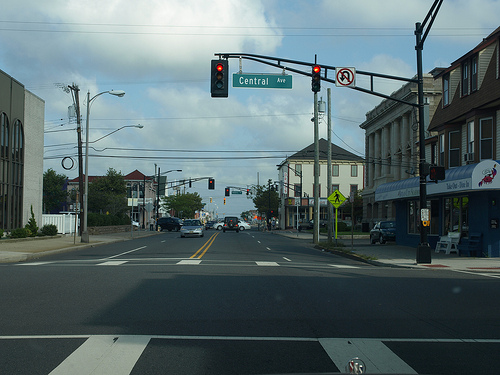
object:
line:
[0, 334, 500, 343]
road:
[1, 215, 499, 374]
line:
[107, 245, 149, 259]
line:
[282, 256, 292, 262]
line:
[197, 232, 220, 259]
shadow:
[76, 269, 499, 373]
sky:
[1, 0, 500, 219]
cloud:
[316, 0, 497, 39]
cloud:
[0, 0, 290, 88]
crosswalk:
[8, 258, 387, 271]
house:
[275, 136, 369, 231]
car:
[179, 219, 205, 239]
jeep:
[222, 216, 240, 233]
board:
[232, 72, 293, 89]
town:
[0, 0, 500, 375]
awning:
[374, 158, 500, 202]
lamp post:
[80, 92, 90, 243]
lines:
[175, 259, 203, 265]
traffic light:
[215, 63, 224, 72]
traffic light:
[313, 65, 322, 74]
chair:
[434, 231, 462, 256]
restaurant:
[358, 70, 437, 226]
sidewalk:
[317, 240, 500, 281]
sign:
[231, 191, 243, 195]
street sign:
[232, 73, 293, 89]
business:
[369, 157, 499, 256]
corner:
[378, 256, 498, 272]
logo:
[344, 356, 367, 375]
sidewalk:
[0, 229, 156, 264]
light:
[209, 181, 212, 184]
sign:
[334, 66, 357, 88]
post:
[414, 21, 432, 266]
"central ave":
[232, 73, 293, 89]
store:
[371, 158, 500, 256]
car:
[212, 219, 252, 231]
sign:
[327, 189, 348, 209]